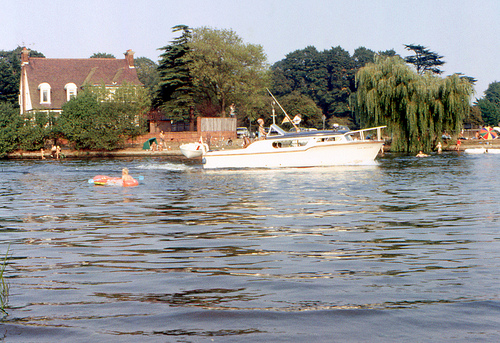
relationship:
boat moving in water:
[191, 89, 401, 183] [186, 198, 434, 284]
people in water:
[52, 163, 256, 192] [224, 185, 367, 265]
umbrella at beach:
[479, 119, 496, 151] [7, 111, 487, 165]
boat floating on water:
[200, 87, 386, 177] [0, 147, 498, 342]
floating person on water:
[81, 163, 149, 197] [0, 147, 498, 342]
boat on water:
[202, 122, 386, 167] [0, 147, 498, 342]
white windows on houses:
[30, 75, 80, 111] [16, 31, 164, 131]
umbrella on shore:
[476, 122, 498, 145] [460, 124, 490, 154]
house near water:
[15, 47, 147, 129] [0, 147, 498, 342]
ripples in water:
[135, 320, 269, 340] [0, 147, 498, 342]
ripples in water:
[174, 222, 306, 244] [0, 147, 498, 342]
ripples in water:
[204, 192, 271, 211] [0, 147, 498, 342]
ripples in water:
[80, 221, 157, 248] [0, 147, 498, 342]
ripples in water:
[391, 232, 482, 256] [0, 147, 498, 342]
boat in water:
[195, 116, 389, 176] [41, 193, 460, 323]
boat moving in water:
[200, 119, 392, 179] [56, 168, 461, 286]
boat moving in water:
[203, 117, 385, 172] [0, 147, 498, 342]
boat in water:
[200, 87, 386, 177] [0, 147, 498, 342]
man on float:
[120, 168, 132, 179] [78, 173, 139, 194]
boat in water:
[196, 88, 387, 167] [252, 187, 444, 297]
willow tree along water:
[358, 53, 471, 158] [0, 147, 498, 342]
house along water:
[10, 37, 155, 134] [37, 202, 458, 327]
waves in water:
[1, 153, 498, 338] [48, 204, 451, 339]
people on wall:
[27, 131, 70, 161] [11, 147, 181, 157]